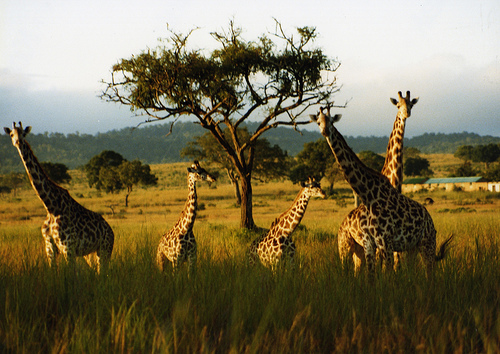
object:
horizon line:
[0, 115, 498, 141]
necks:
[323, 132, 394, 200]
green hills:
[0, 115, 184, 158]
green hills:
[405, 131, 498, 156]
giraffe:
[340, 90, 418, 278]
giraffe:
[309, 107, 454, 280]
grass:
[2, 201, 500, 352]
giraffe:
[246, 177, 331, 272]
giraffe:
[156, 159, 216, 280]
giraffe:
[3, 120, 115, 276]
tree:
[96, 15, 352, 229]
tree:
[182, 127, 296, 206]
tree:
[77, 150, 165, 208]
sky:
[2, 1, 498, 139]